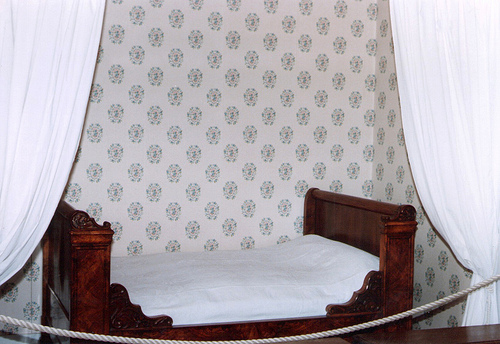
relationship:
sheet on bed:
[108, 260, 340, 309] [41, 188, 416, 340]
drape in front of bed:
[392, 4, 484, 319] [42, 157, 425, 342]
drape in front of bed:
[0, 8, 103, 251] [42, 157, 425, 342]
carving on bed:
[337, 284, 387, 314] [41, 188, 416, 340]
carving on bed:
[109, 289, 152, 331] [41, 188, 416, 340]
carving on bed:
[67, 206, 99, 235] [41, 188, 416, 340]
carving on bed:
[389, 201, 423, 222] [41, 188, 416, 340]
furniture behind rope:
[42, 203, 492, 288] [306, 296, 488, 340]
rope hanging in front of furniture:
[1, 279, 499, 343] [36, 186, 417, 343]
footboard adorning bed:
[36, 198, 131, 331] [41, 188, 416, 340]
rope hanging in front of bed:
[1, 272, 499, 340] [41, 188, 416, 340]